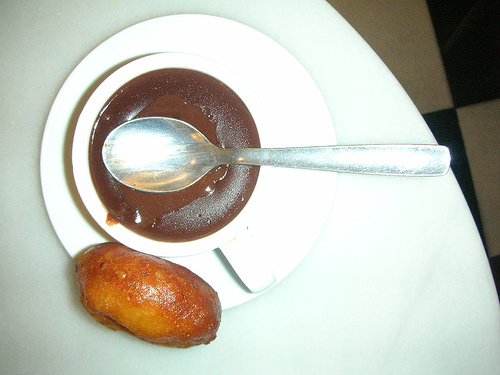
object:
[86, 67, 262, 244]
sauce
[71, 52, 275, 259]
bowl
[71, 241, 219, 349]
pastry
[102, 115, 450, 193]
spoon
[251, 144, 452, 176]
handle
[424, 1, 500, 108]
floor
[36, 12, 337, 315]
plate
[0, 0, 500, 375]
table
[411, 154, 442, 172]
reflection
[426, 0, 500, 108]
tiles